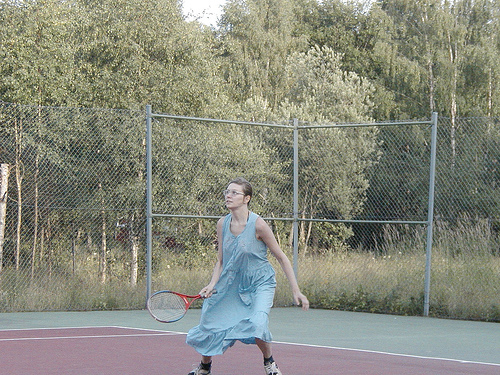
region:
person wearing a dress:
[173, 170, 294, 361]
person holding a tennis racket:
[155, 169, 283, 358]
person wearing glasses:
[211, 160, 253, 220]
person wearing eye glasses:
[218, 181, 251, 206]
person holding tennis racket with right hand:
[153, 174, 238, 330]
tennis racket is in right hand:
[137, 260, 222, 322]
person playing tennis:
[158, 154, 303, 368]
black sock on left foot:
[256, 347, 281, 367]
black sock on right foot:
[196, 356, 211, 367]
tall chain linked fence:
[18, 105, 128, 310]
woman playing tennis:
[133, 150, 341, 372]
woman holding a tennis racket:
[136, 162, 349, 372]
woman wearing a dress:
[138, 168, 303, 363]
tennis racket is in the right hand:
[148, 195, 230, 327]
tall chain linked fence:
[336, 173, 399, 259]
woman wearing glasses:
[213, 167, 255, 217]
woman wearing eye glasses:
[216, 178, 268, 217]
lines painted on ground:
[16, 323, 150, 345]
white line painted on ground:
[337, 325, 425, 370]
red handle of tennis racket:
[176, 283, 216, 314]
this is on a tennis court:
[24, 29, 444, 351]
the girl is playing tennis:
[117, 151, 319, 336]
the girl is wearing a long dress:
[180, 197, 292, 368]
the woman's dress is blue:
[194, 214, 304, 364]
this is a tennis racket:
[131, 286, 204, 332]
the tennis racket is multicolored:
[124, 281, 204, 309]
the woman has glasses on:
[200, 188, 265, 214]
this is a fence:
[60, 104, 448, 197]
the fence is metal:
[61, 105, 480, 184]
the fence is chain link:
[95, 99, 482, 186]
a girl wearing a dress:
[175, 169, 308, 362]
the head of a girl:
[226, 177, 258, 222]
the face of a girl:
[228, 184, 243, 201]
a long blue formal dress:
[207, 203, 273, 349]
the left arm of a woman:
[261, 220, 345, 338]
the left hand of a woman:
[278, 276, 323, 313]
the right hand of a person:
[188, 276, 222, 311]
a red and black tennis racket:
[145, 272, 200, 326]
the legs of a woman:
[186, 324, 276, 369]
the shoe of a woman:
[261, 356, 289, 373]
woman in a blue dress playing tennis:
[144, 164, 313, 372]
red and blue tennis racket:
[138, 282, 220, 327]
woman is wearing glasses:
[219, 177, 254, 211]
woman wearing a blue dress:
[185, 178, 315, 369]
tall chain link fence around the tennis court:
[0, 94, 499, 311]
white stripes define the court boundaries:
[2, 323, 186, 345]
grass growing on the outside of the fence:
[310, 222, 499, 321]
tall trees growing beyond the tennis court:
[3, 0, 493, 244]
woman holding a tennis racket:
[137, 177, 318, 373]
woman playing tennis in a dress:
[138, 168, 318, 369]